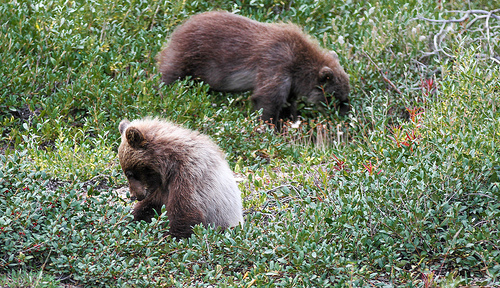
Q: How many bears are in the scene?
A: Two.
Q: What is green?
A: Grass.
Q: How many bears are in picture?
A: Two.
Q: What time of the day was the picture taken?
A: During daytime.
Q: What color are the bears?
A: Brown.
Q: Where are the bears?
A: In the wild.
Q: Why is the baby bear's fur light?
A: Because of sunlight.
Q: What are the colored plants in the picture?
A: Flowers.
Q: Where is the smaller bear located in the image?
A: In the front.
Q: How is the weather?
A: Sunny.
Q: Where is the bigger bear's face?
A: Hidden in the grass.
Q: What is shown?
A: Animals in a field.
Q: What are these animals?
A: Bears.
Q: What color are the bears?
A: Brown.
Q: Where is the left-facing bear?
A: In the front.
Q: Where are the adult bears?
A: There are none.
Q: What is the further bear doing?
A: Nudging through the grass.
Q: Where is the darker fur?
A: Around the bear's eyes.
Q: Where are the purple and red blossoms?
A: Dotted through the grass.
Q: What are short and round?
A: The bear cub's ears.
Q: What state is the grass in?
A: Overgrown.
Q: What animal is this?
A: Bear.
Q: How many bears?
A: Two.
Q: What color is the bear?
A: Brown.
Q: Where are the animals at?
A: Outside in bushes.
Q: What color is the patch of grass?
A: Green.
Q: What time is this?
A: During the day time.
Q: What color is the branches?
A: Gray.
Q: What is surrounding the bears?
A: Shrubs.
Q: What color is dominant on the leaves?
A: Green.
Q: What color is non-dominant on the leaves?
A: Red.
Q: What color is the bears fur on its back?
A: Brown.